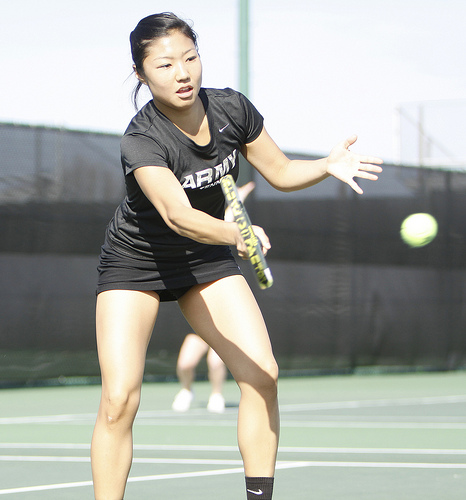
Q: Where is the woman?
A: On the court.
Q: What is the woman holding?
A: A tennis racket.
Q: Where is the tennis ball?
A: In the air.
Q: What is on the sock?
A: A logo.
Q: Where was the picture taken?
A: A tennis court.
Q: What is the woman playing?
A: Tennis.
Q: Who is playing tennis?
A: The woman.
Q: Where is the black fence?
A: Behind the woman.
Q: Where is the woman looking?
A: At the ball.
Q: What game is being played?
A: Tennis.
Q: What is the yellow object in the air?
A: Tennis ball.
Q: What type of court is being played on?
A: Tennis.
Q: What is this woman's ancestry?
A: Asian.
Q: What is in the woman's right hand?
A: Racquet.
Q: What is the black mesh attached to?
A: Fence.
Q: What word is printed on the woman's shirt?
A: Army.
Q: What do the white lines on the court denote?
A: Boundaries.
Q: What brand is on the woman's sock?
A: Nike.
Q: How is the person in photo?
A: Ready to hit tennis ball.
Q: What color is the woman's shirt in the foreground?
A: Black.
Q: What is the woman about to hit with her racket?
A: Tennis ball.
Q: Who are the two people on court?
A: Tennis players.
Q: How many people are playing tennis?
A: Two.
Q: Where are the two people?
A: Tennis court.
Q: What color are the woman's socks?
A: Black.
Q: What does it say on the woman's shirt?
A: Army.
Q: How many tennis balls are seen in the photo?
A: One.